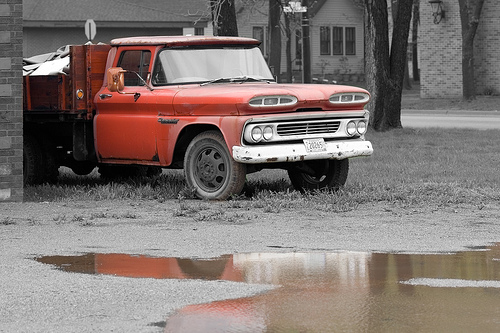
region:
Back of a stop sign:
[78, 17, 98, 38]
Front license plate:
[296, 136, 333, 155]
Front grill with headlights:
[238, 116, 378, 140]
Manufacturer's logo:
[150, 112, 185, 129]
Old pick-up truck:
[13, 23, 394, 205]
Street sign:
[269, 0, 325, 82]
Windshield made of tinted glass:
[135, 33, 282, 88]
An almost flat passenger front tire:
[165, 123, 260, 208]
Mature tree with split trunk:
[357, 0, 419, 142]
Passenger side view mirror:
[97, 61, 156, 105]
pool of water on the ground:
[31, 222, 499, 331]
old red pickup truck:
[11, 14, 404, 207]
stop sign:
[65, 12, 107, 44]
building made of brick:
[393, 4, 498, 117]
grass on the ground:
[353, 121, 490, 209]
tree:
[356, 2, 423, 153]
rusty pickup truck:
[14, 29, 384, 218]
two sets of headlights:
[231, 80, 380, 150]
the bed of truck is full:
[16, 40, 102, 113]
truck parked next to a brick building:
[6, 24, 387, 206]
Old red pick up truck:
[21, 29, 374, 204]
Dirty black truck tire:
[180, 128, 248, 199]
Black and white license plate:
[302, 134, 329, 152]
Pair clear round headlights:
[248, 122, 275, 142]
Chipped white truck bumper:
[230, 136, 375, 165]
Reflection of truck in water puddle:
[83, 248, 309, 331]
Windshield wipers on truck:
[196, 76, 278, 87]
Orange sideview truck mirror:
[103, 66, 127, 96]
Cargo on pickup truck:
[22, 42, 104, 77]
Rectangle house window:
[318, 23, 330, 55]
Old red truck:
[33, 27, 392, 185]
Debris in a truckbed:
[10, 24, 105, 93]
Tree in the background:
[367, 0, 434, 131]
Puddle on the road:
[73, 241, 499, 328]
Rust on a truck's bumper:
[241, 140, 390, 170]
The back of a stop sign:
[74, 14, 106, 44]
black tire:
[167, 112, 256, 210]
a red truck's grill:
[242, 76, 370, 150]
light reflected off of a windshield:
[156, 29, 276, 86]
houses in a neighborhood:
[283, 5, 499, 77]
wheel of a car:
[190, 165, 214, 206]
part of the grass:
[272, 195, 279, 211]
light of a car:
[255, 119, 265, 148]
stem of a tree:
[394, 77, 401, 93]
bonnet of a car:
[294, 89, 314, 106]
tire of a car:
[234, 162, 239, 186]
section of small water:
[338, 299, 355, 319]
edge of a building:
[453, 62, 464, 88]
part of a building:
[474, 55, 486, 78]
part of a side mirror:
[122, 69, 127, 77]